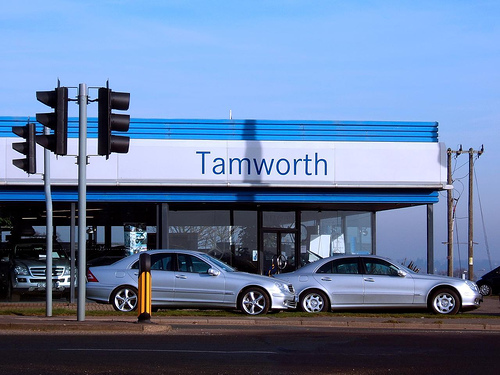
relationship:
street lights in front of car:
[10, 76, 131, 322] [270, 252, 481, 310]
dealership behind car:
[1, 115, 453, 274] [270, 252, 481, 310]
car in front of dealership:
[84, 248, 297, 317] [1, 115, 453, 274]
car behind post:
[84, 247, 300, 317] [135, 252, 155, 319]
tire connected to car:
[110, 285, 141, 312] [84, 247, 300, 317]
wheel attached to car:
[237, 285, 270, 316] [84, 247, 300, 317]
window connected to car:
[176, 253, 211, 273] [84, 247, 300, 317]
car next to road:
[270, 252, 481, 310] [0, 313, 498, 375]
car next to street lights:
[270, 252, 481, 310] [10, 76, 131, 322]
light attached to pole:
[96, 83, 131, 158] [78, 84, 88, 319]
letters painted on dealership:
[196, 149, 329, 178] [1, 115, 453, 274]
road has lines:
[0, 317, 498, 373] [55, 347, 276, 356]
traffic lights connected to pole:
[33, 79, 132, 157] [78, 84, 88, 319]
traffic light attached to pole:
[11, 122, 36, 175] [42, 127, 54, 317]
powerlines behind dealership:
[447, 145, 482, 279] [1, 115, 453, 274]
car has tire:
[271, 252, 485, 311] [431, 288, 459, 314]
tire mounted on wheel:
[108, 285, 141, 313] [112, 283, 139, 311]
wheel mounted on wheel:
[237, 285, 271, 316] [240, 290, 267, 314]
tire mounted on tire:
[297, 289, 329, 314] [297, 288, 328, 314]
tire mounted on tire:
[426, 286, 460, 316] [429, 286, 459, 315]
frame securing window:
[157, 202, 264, 274] [166, 205, 260, 275]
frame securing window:
[255, 207, 301, 234] [261, 206, 295, 227]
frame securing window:
[291, 202, 379, 267] [299, 209, 374, 263]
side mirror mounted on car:
[206, 268, 219, 276] [84, 247, 300, 317]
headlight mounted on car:
[276, 281, 288, 294] [84, 247, 300, 317]